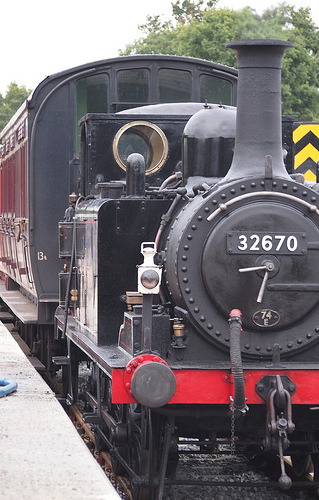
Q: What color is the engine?
A: Black.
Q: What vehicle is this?
A: Train.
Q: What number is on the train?
A: 32670.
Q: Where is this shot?
A: Platform.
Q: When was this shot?
A: Daytime.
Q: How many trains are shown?
A: 1.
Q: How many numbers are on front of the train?
A: 5.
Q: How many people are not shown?
A: 0.